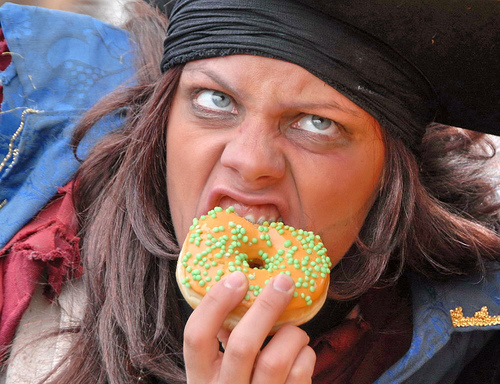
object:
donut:
[174, 204, 332, 327]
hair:
[69, 81, 167, 377]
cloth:
[0, 8, 88, 194]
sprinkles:
[201, 222, 259, 255]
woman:
[0, 0, 500, 354]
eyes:
[181, 81, 247, 125]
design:
[448, 295, 499, 328]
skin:
[163, 60, 365, 192]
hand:
[178, 269, 321, 384]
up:
[193, 22, 356, 139]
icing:
[188, 223, 331, 308]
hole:
[236, 246, 273, 277]